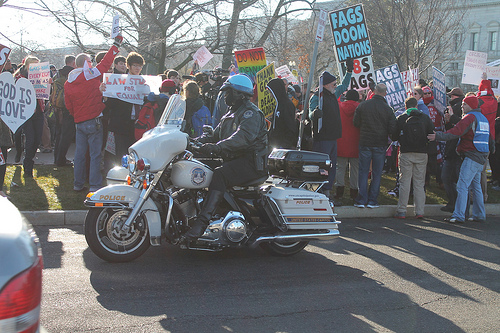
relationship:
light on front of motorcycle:
[117, 150, 134, 169] [76, 111, 347, 268]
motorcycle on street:
[81, 90, 344, 264] [30, 217, 499, 329]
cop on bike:
[190, 74, 270, 254] [82, 96, 342, 266]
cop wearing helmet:
[190, 74, 270, 254] [218, 66, 259, 103]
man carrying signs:
[63, 32, 123, 196] [319, 9, 375, 98]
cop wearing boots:
[190, 71, 270, 254] [181, 185, 263, 241]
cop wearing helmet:
[190, 74, 270, 254] [219, 73, 254, 98]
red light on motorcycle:
[135, 157, 144, 172] [81, 78, 345, 256]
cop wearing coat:
[190, 74, 270, 254] [201, 100, 268, 160]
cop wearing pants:
[190, 74, 270, 254] [182, 151, 274, 254]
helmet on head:
[218, 73, 253, 101] [220, 71, 252, 106]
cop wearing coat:
[190, 74, 270, 254] [201, 103, 281, 163]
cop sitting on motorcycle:
[190, 74, 270, 254] [81, 90, 344, 264]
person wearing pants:
[427, 95, 489, 223] [452, 155, 487, 218]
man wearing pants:
[390, 96, 435, 219] [385, 139, 442, 231]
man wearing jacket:
[352, 82, 400, 209] [348, 92, 401, 154]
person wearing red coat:
[333, 80, 364, 203] [340, 101, 357, 156]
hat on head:
[310, 66, 333, 83] [316, 70, 337, 93]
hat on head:
[461, 96, 481, 108] [461, 92, 481, 119]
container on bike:
[260, 180, 342, 232] [93, 115, 326, 261]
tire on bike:
[85, 195, 155, 263] [118, 132, 218, 238]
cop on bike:
[190, 74, 270, 254] [91, 101, 333, 255]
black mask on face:
[220, 92, 243, 106] [213, 70, 258, 107]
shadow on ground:
[72, 253, 408, 330] [64, 218, 446, 324]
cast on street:
[362, 225, 494, 307] [60, 220, 415, 329]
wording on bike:
[98, 190, 131, 205] [91, 101, 333, 255]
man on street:
[389, 89, 444, 230] [26, 172, 485, 325]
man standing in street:
[368, 50, 401, 205] [17, 189, 499, 323]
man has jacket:
[63, 30, 126, 210] [61, 66, 116, 126]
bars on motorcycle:
[188, 126, 270, 161] [96, 121, 351, 249]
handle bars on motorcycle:
[185, 132, 198, 158] [96, 121, 351, 249]